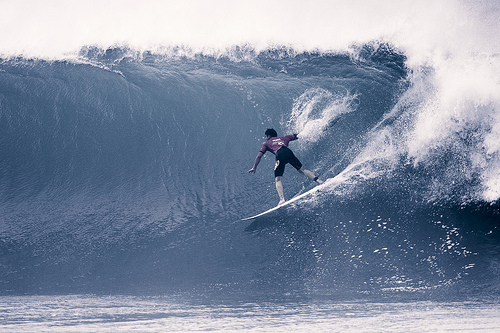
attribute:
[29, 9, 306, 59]
skies — clear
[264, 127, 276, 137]
hair — black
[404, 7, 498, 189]
whitewater — White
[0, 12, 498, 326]
wave — large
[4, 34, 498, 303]
wave — ruffled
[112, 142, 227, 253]
water — spray 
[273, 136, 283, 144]
writing — white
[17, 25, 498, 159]
wave — huge, whitecapped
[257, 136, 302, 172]
wet suit — purple, black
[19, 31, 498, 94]
foam — white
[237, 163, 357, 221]
surfboard — white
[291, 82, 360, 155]
foam — white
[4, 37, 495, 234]
wave — large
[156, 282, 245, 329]
water — white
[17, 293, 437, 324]
ocean water — calm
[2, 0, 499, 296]
wave — big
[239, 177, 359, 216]
surfboard — cutting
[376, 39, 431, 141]
ocean spray — white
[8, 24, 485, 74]
crest — white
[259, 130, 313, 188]
suit — red, black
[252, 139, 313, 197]
outfit — purple, black